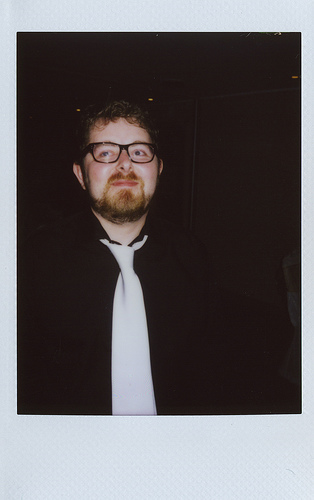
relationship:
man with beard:
[61, 112, 240, 417] [108, 169, 150, 218]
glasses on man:
[91, 138, 156, 170] [61, 112, 240, 417]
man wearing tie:
[61, 112, 240, 417] [102, 254, 157, 414]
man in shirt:
[61, 112, 240, 417] [188, 285, 247, 360]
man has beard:
[61, 112, 240, 417] [108, 169, 150, 218]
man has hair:
[61, 112, 240, 417] [94, 97, 147, 124]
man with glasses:
[61, 112, 240, 417] [91, 138, 156, 170]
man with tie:
[61, 112, 240, 417] [102, 254, 157, 414]